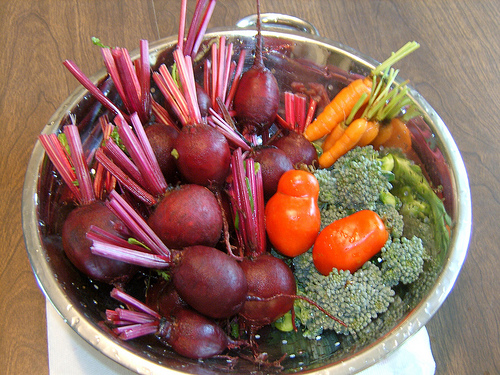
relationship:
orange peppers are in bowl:
[257, 164, 389, 274] [12, 17, 484, 372]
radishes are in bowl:
[85, 67, 284, 351] [12, 17, 484, 372]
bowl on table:
[12, 17, 484, 372] [0, 0, 499, 374]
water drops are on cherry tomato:
[290, 213, 302, 223] [265, 168, 322, 257]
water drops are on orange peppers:
[339, 231, 356, 243] [311, 210, 392, 276]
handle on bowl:
[236, 12, 320, 45] [12, 17, 484, 372]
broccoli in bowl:
[315, 144, 390, 211] [12, 17, 484, 372]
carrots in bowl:
[299, 40, 412, 165] [302, 74, 474, 374]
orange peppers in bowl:
[311, 210, 392, 276] [12, 17, 484, 372]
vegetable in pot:
[37, 0, 436, 369] [21, 9, 471, 374]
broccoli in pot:
[312, 144, 394, 212] [21, 9, 471, 374]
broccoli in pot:
[296, 259, 419, 350] [21, 9, 471, 374]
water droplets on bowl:
[63, 303, 103, 348] [12, 17, 484, 372]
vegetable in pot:
[41, 32, 323, 367] [21, 9, 471, 374]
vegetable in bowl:
[37, 0, 436, 369] [20, 12, 472, 374]